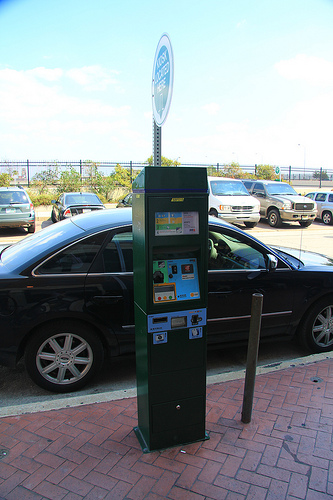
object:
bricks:
[241, 449, 262, 471]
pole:
[240, 292, 263, 423]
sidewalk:
[0, 352, 332, 498]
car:
[0, 207, 333, 395]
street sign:
[150, 33, 174, 128]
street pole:
[152, 111, 162, 167]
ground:
[0, 359, 333, 500]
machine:
[131, 164, 210, 450]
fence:
[0, 160, 333, 189]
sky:
[0, 0, 333, 168]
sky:
[48, 6, 126, 98]